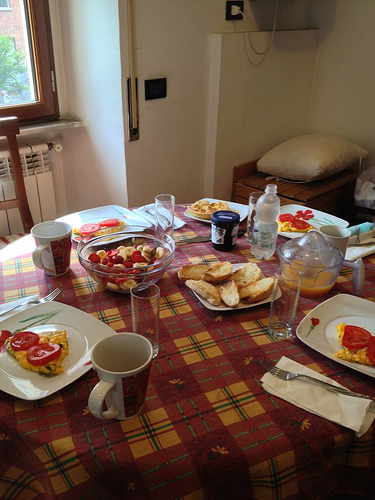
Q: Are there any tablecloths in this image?
A: Yes, there is a tablecloth.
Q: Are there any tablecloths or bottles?
A: Yes, there is a tablecloth.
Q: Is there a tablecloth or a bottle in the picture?
A: Yes, there is a tablecloth.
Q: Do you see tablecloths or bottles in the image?
A: Yes, there is a tablecloth.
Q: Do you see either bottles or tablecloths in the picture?
A: Yes, there is a tablecloth.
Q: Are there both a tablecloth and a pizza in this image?
A: No, there is a tablecloth but no pizzas.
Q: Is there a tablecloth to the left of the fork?
A: Yes, there is a tablecloth to the left of the fork.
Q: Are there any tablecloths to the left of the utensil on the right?
A: Yes, there is a tablecloth to the left of the fork.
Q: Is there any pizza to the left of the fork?
A: No, there is a tablecloth to the left of the fork.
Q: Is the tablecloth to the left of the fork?
A: Yes, the tablecloth is to the left of the fork.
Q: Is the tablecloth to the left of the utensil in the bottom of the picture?
A: Yes, the tablecloth is to the left of the fork.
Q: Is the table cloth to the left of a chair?
A: No, the table cloth is to the left of the fork.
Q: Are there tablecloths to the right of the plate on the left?
A: Yes, there is a tablecloth to the right of the plate.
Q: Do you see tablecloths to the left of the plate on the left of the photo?
A: No, the tablecloth is to the right of the plate.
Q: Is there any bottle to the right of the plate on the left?
A: No, there is a tablecloth to the right of the plate.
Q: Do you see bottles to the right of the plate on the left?
A: No, there is a tablecloth to the right of the plate.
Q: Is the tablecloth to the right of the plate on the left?
A: Yes, the tablecloth is to the right of the plate.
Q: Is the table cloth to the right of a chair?
A: No, the table cloth is to the right of the plate.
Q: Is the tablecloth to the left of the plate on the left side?
A: No, the tablecloth is to the right of the plate.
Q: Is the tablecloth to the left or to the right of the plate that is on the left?
A: The tablecloth is to the right of the plate.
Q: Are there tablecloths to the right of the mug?
A: Yes, there is a tablecloth to the right of the mug.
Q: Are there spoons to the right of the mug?
A: No, there is a tablecloth to the right of the mug.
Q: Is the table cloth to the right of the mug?
A: Yes, the table cloth is to the right of the mug.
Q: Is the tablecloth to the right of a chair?
A: No, the tablecloth is to the right of the mug.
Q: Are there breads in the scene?
A: Yes, there is a bread.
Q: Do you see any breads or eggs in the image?
A: Yes, there is a bread.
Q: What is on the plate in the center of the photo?
A: The bread is on the plate.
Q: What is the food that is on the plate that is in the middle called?
A: The food is a bread.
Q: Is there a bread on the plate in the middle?
A: Yes, there is a bread on the plate.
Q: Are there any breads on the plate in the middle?
A: Yes, there is a bread on the plate.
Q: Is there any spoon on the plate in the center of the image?
A: No, there is a bread on the plate.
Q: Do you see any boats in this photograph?
A: No, there are no boats.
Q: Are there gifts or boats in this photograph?
A: No, there are no boats or gifts.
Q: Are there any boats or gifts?
A: No, there are no boats or gifts.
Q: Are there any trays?
A: No, there are no trays.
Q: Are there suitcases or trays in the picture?
A: No, there are no trays or suitcases.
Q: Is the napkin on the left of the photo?
A: No, the napkin is on the right of the image.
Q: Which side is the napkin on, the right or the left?
A: The napkin is on the right of the image.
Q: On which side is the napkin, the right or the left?
A: The napkin is on the right of the image.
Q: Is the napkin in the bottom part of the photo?
A: Yes, the napkin is in the bottom of the image.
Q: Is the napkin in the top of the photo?
A: No, the napkin is in the bottom of the image.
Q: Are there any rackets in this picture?
A: No, there are no rackets.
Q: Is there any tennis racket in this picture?
A: No, there are no rackets.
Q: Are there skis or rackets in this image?
A: No, there are no rackets or skis.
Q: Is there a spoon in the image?
A: No, there are no spoons.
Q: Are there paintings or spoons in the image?
A: No, there are no spoons or paintings.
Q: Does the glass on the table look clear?
A: Yes, the glass is clear.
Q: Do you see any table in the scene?
A: Yes, there is a table.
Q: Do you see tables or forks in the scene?
A: Yes, there is a table.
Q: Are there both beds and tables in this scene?
A: No, there is a table but no beds.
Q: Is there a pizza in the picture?
A: No, there are no pizzas.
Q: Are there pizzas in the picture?
A: No, there are no pizzas.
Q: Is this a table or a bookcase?
A: This is a table.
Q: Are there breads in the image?
A: Yes, there is a bread.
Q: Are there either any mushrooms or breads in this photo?
A: Yes, there is a bread.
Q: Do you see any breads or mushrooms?
A: Yes, there is a bread.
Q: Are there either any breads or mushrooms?
A: Yes, there is a bread.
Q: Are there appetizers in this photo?
A: No, there are no appetizers.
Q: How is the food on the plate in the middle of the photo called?
A: The food is a bread.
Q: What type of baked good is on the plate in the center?
A: The food is a bread.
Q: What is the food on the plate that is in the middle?
A: The food is a bread.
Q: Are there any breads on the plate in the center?
A: Yes, there is a bread on the plate.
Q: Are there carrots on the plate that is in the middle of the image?
A: No, there is a bread on the plate.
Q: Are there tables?
A: Yes, there is a table.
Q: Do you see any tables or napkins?
A: Yes, there is a table.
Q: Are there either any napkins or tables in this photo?
A: Yes, there is a table.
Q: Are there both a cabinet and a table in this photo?
A: No, there is a table but no cabinets.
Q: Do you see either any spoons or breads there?
A: Yes, there is a bread.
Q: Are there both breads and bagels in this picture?
A: No, there is a bread but no bagels.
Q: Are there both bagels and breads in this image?
A: No, there is a bread but no bagels.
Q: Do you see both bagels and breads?
A: No, there is a bread but no bagels.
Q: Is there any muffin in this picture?
A: No, there are no muffins.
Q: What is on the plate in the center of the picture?
A: The bread is on the plate.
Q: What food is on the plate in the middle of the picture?
A: The food is a bread.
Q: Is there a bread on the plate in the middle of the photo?
A: Yes, there is a bread on the plate.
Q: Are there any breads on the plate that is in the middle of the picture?
A: Yes, there is a bread on the plate.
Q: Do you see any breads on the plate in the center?
A: Yes, there is a bread on the plate.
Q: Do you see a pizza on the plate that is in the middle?
A: No, there is a bread on the plate.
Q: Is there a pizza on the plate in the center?
A: No, there is a bread on the plate.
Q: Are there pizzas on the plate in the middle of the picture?
A: No, there is a bread on the plate.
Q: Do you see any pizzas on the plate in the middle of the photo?
A: No, there is a bread on the plate.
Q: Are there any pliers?
A: No, there are no pliers.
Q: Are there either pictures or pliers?
A: No, there are no pliers or pictures.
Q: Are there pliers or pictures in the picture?
A: No, there are no pliers or pictures.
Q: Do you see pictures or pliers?
A: No, there are no pliers or pictures.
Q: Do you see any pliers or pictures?
A: No, there are no pliers or pictures.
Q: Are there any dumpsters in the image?
A: No, there are no dumpsters.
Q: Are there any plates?
A: Yes, there is a plate.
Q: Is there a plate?
A: Yes, there is a plate.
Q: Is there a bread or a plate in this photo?
A: Yes, there is a plate.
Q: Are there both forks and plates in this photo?
A: Yes, there are both a plate and a fork.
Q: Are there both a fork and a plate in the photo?
A: Yes, there are both a plate and a fork.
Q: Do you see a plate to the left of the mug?
A: Yes, there is a plate to the left of the mug.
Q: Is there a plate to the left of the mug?
A: Yes, there is a plate to the left of the mug.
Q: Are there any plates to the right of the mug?
A: No, the plate is to the left of the mug.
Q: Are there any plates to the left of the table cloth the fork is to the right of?
A: Yes, there is a plate to the left of the tablecloth.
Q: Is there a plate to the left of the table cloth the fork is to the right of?
A: Yes, there is a plate to the left of the tablecloth.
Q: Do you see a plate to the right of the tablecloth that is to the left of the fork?
A: No, the plate is to the left of the tablecloth.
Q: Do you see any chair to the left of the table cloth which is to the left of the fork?
A: No, there is a plate to the left of the tablecloth.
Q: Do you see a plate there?
A: Yes, there is a plate.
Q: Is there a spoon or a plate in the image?
A: Yes, there is a plate.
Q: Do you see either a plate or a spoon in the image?
A: Yes, there is a plate.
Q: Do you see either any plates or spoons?
A: Yes, there is a plate.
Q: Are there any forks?
A: Yes, there is a fork.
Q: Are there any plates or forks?
A: Yes, there is a fork.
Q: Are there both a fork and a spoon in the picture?
A: No, there is a fork but no spoons.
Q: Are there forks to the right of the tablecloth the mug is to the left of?
A: Yes, there is a fork to the right of the tablecloth.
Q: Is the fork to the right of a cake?
A: No, the fork is to the right of the tablecloth.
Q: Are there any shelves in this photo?
A: No, there are no shelves.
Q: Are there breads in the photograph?
A: Yes, there is a bread.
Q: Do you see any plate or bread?
A: Yes, there is a bread.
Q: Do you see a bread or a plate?
A: Yes, there is a bread.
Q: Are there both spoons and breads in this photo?
A: No, there is a bread but no spoons.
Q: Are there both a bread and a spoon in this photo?
A: No, there is a bread but no spoons.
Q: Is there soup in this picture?
A: No, there is no soup.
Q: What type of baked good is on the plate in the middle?
A: The food is a bread.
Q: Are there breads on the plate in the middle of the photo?
A: Yes, there is a bread on the plate.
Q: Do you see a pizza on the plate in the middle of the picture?
A: No, there is a bread on the plate.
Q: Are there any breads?
A: Yes, there is a bread.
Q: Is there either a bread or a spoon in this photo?
A: Yes, there is a bread.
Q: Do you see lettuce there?
A: No, there is no lettuce.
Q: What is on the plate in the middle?
A: The bread is on the plate.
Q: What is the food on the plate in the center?
A: The food is a bread.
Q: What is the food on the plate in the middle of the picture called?
A: The food is a bread.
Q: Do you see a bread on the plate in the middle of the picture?
A: Yes, there is a bread on the plate.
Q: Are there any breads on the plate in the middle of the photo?
A: Yes, there is a bread on the plate.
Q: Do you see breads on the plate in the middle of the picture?
A: Yes, there is a bread on the plate.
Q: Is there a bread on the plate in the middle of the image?
A: Yes, there is a bread on the plate.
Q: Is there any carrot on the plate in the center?
A: No, there is a bread on the plate.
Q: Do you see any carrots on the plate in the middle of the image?
A: No, there is a bread on the plate.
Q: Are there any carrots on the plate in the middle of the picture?
A: No, there is a bread on the plate.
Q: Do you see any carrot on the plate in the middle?
A: No, there is a bread on the plate.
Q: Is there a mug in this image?
A: Yes, there is a mug.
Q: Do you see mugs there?
A: Yes, there is a mug.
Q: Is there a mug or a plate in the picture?
A: Yes, there is a mug.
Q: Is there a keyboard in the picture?
A: No, there are no keyboards.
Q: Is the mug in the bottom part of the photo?
A: Yes, the mug is in the bottom of the image.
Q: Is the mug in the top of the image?
A: No, the mug is in the bottom of the image.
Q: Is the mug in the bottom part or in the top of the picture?
A: The mug is in the bottom of the image.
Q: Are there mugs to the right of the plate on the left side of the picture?
A: Yes, there is a mug to the right of the plate.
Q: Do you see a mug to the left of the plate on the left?
A: No, the mug is to the right of the plate.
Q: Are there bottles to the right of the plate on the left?
A: No, there is a mug to the right of the plate.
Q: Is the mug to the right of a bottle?
A: No, the mug is to the right of a plate.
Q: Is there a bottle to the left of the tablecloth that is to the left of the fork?
A: No, there is a mug to the left of the tablecloth.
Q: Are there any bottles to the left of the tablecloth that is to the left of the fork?
A: No, there is a mug to the left of the tablecloth.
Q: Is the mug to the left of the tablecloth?
A: Yes, the mug is to the left of the tablecloth.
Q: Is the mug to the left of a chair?
A: No, the mug is to the left of the tablecloth.